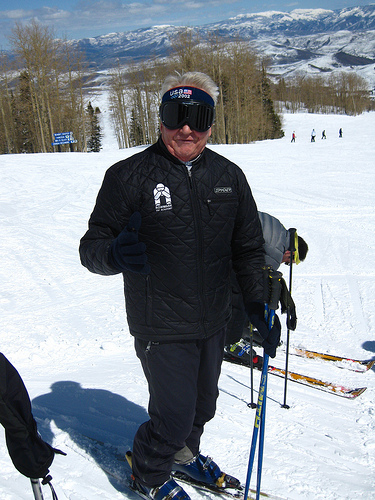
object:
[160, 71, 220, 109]
gray hair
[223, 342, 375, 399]
skis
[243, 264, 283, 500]
poles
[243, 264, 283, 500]
pair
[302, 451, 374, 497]
snow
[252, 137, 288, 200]
ground snow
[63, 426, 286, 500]
skies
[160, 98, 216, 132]
sunglasses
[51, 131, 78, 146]
sign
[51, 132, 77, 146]
lettering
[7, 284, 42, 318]
snow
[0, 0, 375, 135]
mountain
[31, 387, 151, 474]
tracks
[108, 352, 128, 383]
snow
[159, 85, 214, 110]
headband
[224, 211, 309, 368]
person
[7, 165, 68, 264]
snow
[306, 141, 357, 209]
snow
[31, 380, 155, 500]
shadow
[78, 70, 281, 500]
human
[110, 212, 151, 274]
gloves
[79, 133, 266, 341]
coat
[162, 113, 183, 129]
eye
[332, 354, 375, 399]
front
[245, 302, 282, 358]
hand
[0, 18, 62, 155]
trees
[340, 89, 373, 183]
ground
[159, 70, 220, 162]
head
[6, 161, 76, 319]
ground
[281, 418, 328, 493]
ground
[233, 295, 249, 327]
knee